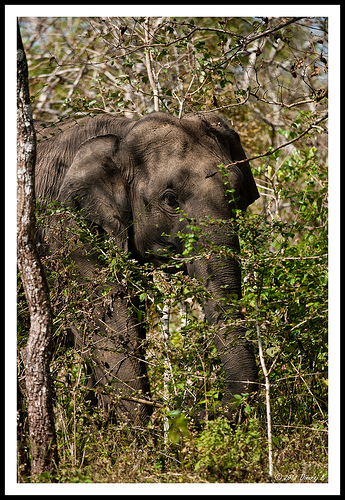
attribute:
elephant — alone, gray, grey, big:
[44, 101, 277, 459]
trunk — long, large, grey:
[200, 267, 262, 418]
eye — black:
[156, 191, 181, 205]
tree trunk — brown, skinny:
[18, 269, 67, 483]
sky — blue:
[307, 30, 325, 37]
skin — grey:
[72, 122, 128, 138]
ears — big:
[77, 140, 130, 211]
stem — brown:
[21, 313, 57, 402]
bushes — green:
[176, 417, 270, 464]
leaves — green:
[187, 54, 229, 82]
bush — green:
[67, 414, 135, 461]